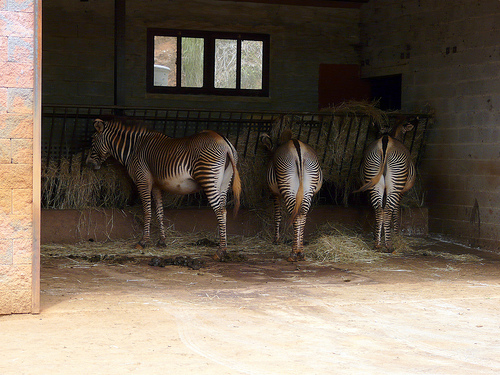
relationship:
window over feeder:
[146, 25, 271, 98] [45, 113, 435, 188]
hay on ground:
[311, 227, 377, 264] [0, 237, 499, 374]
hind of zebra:
[275, 140, 322, 197] [260, 126, 324, 265]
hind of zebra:
[203, 130, 238, 190] [86, 113, 244, 255]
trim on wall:
[34, 1, 42, 314] [0, 0, 499, 314]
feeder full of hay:
[45, 113, 435, 188] [318, 97, 389, 207]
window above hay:
[146, 25, 271, 98] [223, 132, 272, 207]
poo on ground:
[150, 254, 204, 270] [0, 237, 499, 374]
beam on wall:
[114, 3, 125, 118] [0, 0, 499, 314]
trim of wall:
[34, 1, 42, 314] [0, 0, 499, 314]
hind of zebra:
[275, 140, 322, 197] [86, 113, 244, 255]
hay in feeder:
[318, 97, 389, 207] [45, 113, 435, 188]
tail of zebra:
[228, 151, 242, 216] [86, 113, 244, 255]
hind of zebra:
[363, 138, 409, 198] [356, 123, 419, 257]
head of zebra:
[85, 118, 112, 175] [86, 113, 244, 255]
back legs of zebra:
[289, 196, 307, 261] [260, 126, 324, 265]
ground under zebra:
[0, 237, 499, 374] [86, 113, 244, 255]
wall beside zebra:
[0, 0, 499, 314] [356, 123, 419, 257]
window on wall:
[146, 25, 271, 98] [0, 0, 499, 314]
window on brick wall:
[146, 25, 271, 98] [0, 0, 499, 314]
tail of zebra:
[289, 157, 306, 230] [260, 126, 324, 265]